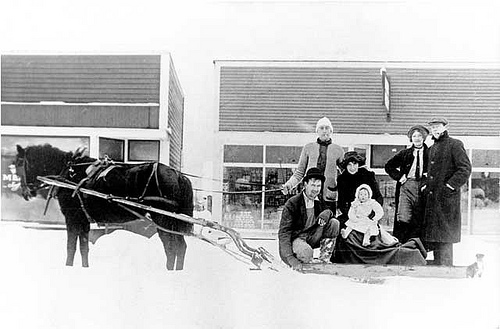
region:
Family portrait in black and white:
[0, 41, 496, 300]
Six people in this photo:
[269, 100, 479, 270]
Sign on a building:
[372, 65, 404, 125]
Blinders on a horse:
[10, 140, 35, 205]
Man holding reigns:
[198, 109, 344, 217]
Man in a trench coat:
[427, 111, 475, 264]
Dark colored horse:
[10, 127, 219, 286]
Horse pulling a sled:
[8, 128, 495, 305]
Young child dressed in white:
[342, 179, 384, 254]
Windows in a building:
[221, 138, 498, 233]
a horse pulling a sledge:
[5, 137, 488, 291]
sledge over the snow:
[251, 248, 492, 289]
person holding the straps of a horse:
[6, 88, 344, 207]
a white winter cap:
[306, 110, 341, 153]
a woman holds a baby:
[333, 148, 393, 252]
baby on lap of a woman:
[327, 148, 385, 246]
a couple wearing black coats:
[384, 110, 473, 268]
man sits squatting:
[272, 162, 342, 269]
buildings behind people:
[6, 40, 494, 262]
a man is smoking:
[301, 110, 346, 162]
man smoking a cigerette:
[302, 114, 339, 177]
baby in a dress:
[342, 185, 391, 240]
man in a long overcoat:
[425, 118, 470, 266]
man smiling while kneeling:
[285, 176, 333, 276]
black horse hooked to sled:
[10, 137, 203, 269]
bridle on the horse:
[86, 158, 146, 174]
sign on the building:
[374, 68, 406, 124]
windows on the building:
[225, 138, 278, 183]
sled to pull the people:
[314, 262, 464, 292]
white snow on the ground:
[164, 278, 343, 321]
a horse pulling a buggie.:
[12, 123, 205, 250]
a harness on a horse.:
[29, 159, 277, 282]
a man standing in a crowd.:
[275, 106, 357, 234]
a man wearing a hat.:
[398, 96, 473, 276]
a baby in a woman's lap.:
[341, 182, 384, 248]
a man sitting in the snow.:
[267, 171, 341, 285]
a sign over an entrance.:
[367, 63, 405, 130]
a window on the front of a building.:
[214, 143, 269, 245]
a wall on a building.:
[156, 40, 193, 174]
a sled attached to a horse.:
[269, 203, 491, 315]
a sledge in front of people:
[284, 254, 490, 287]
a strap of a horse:
[8, 135, 298, 262]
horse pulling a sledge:
[2, 132, 304, 278]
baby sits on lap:
[331, 175, 387, 247]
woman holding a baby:
[334, 145, 391, 262]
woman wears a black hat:
[334, 145, 378, 182]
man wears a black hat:
[287, 165, 338, 215]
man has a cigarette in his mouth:
[299, 108, 348, 160]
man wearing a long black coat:
[420, 111, 470, 261]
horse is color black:
[10, 140, 202, 269]